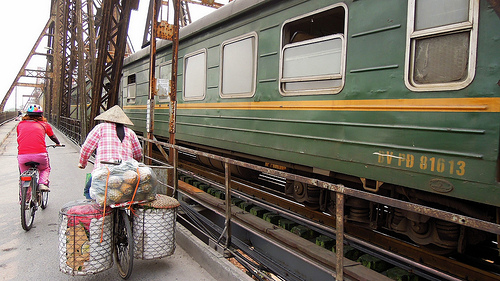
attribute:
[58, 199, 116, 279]
basket — large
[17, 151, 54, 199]
pants — pink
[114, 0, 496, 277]
passenger train — green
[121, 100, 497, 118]
stripe — yellow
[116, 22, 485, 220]
train — green, yellow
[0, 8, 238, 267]
scene —  outside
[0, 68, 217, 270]
scene — day time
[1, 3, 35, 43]
sky — white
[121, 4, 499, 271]
train — green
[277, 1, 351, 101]
window — open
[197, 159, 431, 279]
fence — metal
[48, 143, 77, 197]
pavement — gray